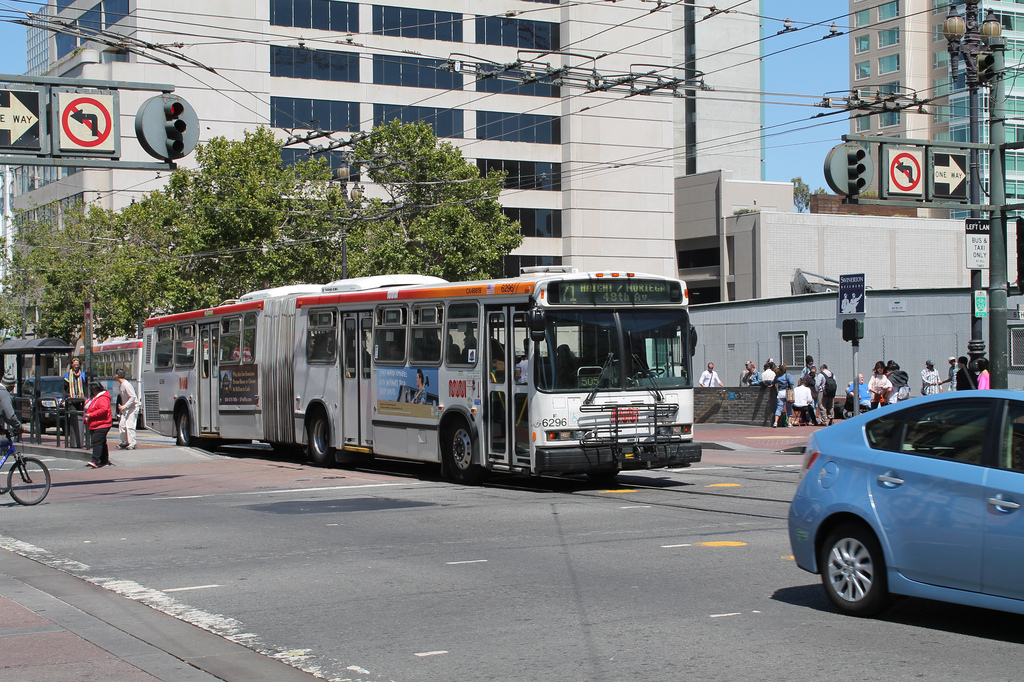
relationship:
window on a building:
[276, 43, 357, 79] [7, 9, 761, 331]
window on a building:
[475, 15, 561, 51] [10, 1, 1023, 420]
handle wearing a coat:
[83, 382, 112, 468] [78, 387, 116, 436]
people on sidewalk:
[772, 365, 794, 428] [697, 419, 815, 455]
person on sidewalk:
[868, 355, 894, 407] [701, 420, 835, 453]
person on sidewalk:
[694, 354, 720, 403] [672, 383, 828, 453]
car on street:
[782, 384, 1021, 622] [0, 425, 1024, 679]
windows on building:
[247, 32, 376, 101] [203, 16, 679, 282]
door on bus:
[488, 323, 552, 455] [105, 247, 719, 500]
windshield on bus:
[542, 303, 705, 383] [131, 262, 702, 500]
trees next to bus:
[227, 110, 511, 245] [125, 251, 711, 483]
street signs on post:
[826, 119, 979, 209] [907, 20, 990, 416]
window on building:
[270, 45, 360, 83] [34, 9, 825, 366]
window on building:
[360, 95, 469, 153] [7, 9, 761, 331]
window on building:
[257, 69, 434, 161] [13, 9, 765, 280]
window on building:
[483, 6, 559, 67] [13, 9, 765, 280]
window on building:
[674, 207, 749, 299] [674, 161, 979, 423]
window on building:
[474, 201, 578, 234] [13, 9, 765, 280]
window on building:
[49, 16, 192, 77] [13, 9, 765, 280]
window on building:
[851, 29, 906, 79] [13, 9, 765, 280]